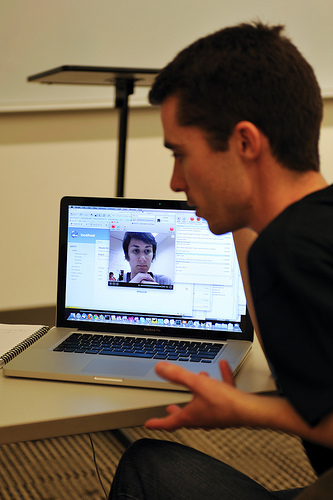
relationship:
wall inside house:
[32, 28, 97, 73] [236, 28, 294, 68]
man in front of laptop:
[129, 56, 332, 385] [3, 196, 254, 392]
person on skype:
[109, 233, 181, 291] [70, 229, 115, 250]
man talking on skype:
[129, 56, 332, 385] [70, 229, 115, 250]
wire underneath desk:
[82, 434, 109, 498] [0, 322, 279, 445]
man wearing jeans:
[129, 56, 332, 385] [106, 438, 273, 500]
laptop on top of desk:
[7, 192, 259, 397] [5, 327, 318, 500]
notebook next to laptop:
[0, 325, 54, 367] [7, 192, 259, 397]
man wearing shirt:
[129, 56, 332, 385] [244, 183, 330, 426]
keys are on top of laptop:
[55, 332, 224, 367] [7, 192, 259, 397]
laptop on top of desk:
[3, 196, 254, 392] [0, 322, 279, 445]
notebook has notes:
[0, 325, 54, 367] [7, 324, 29, 340]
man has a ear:
[129, 56, 332, 385] [236, 118, 261, 163]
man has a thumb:
[129, 56, 332, 385] [154, 361, 214, 393]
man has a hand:
[129, 56, 332, 385] [147, 359, 252, 437]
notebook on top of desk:
[0, 325, 54, 367] [0, 322, 279, 445]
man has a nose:
[129, 56, 332, 385] [168, 172, 186, 195]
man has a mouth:
[129, 56, 332, 385] [185, 201, 206, 219]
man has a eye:
[129, 56, 332, 385] [167, 147, 189, 165]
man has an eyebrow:
[129, 56, 332, 385] [160, 140, 190, 151]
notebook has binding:
[0, 325, 54, 367] [19, 327, 51, 355]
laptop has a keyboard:
[7, 192, 259, 397] [48, 321, 230, 382]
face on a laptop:
[126, 238, 154, 273] [7, 192, 259, 397]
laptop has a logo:
[7, 192, 259, 397] [139, 325, 170, 334]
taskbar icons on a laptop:
[66, 310, 243, 331] [7, 192, 259, 397]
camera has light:
[145, 199, 170, 213] [151, 203, 165, 209]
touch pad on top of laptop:
[75, 355, 152, 376] [7, 192, 259, 397]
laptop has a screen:
[7, 192, 259, 397] [76, 208, 239, 316]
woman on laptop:
[109, 233, 181, 291] [7, 192, 259, 397]